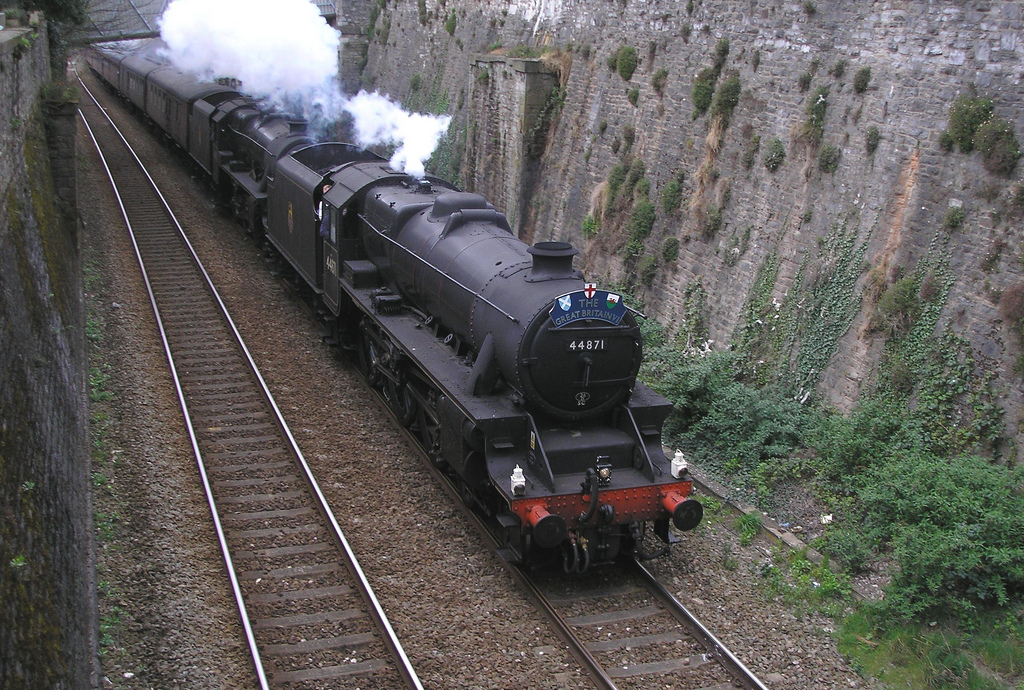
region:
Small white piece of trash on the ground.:
[822, 499, 839, 516]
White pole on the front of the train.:
[482, 446, 534, 513]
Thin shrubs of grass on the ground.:
[61, 315, 189, 680]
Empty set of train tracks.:
[146, 382, 382, 648]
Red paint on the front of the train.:
[514, 478, 718, 536]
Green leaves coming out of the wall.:
[582, 37, 660, 124]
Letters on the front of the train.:
[541, 282, 631, 343]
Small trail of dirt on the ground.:
[947, 634, 1005, 686]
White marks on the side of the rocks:
[503, 0, 596, 35]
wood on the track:
[283, 650, 344, 677]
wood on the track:
[244, 553, 298, 589]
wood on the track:
[317, 534, 337, 551]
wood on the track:
[310, 516, 331, 532]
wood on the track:
[596, 587, 632, 606]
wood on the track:
[690, 644, 745, 670]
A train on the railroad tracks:
[84, 26, 707, 574]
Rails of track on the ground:
[62, 55, 443, 686]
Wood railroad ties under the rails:
[230, 570, 393, 640]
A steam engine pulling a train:
[319, 158, 712, 564]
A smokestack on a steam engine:
[524, 232, 583, 274]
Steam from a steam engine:
[153, 0, 455, 175]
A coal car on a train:
[261, 140, 376, 306]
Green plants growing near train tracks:
[647, 333, 1021, 622]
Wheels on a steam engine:
[360, 316, 474, 494]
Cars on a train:
[138, 63, 231, 153]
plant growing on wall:
[973, 111, 1019, 181]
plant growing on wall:
[945, 89, 987, 157]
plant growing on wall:
[876, 272, 919, 321]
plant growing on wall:
[616, 124, 643, 148]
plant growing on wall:
[664, 168, 685, 214]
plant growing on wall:
[610, 47, 648, 82]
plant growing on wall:
[613, 124, 637, 148]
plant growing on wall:
[597, 155, 630, 187]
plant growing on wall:
[663, 225, 684, 264]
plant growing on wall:
[754, 121, 787, 176]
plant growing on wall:
[936, 79, 991, 160]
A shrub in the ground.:
[939, 74, 990, 152]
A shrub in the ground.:
[969, 130, 995, 181]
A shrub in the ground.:
[860, 115, 900, 166]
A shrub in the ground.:
[716, 64, 748, 129]